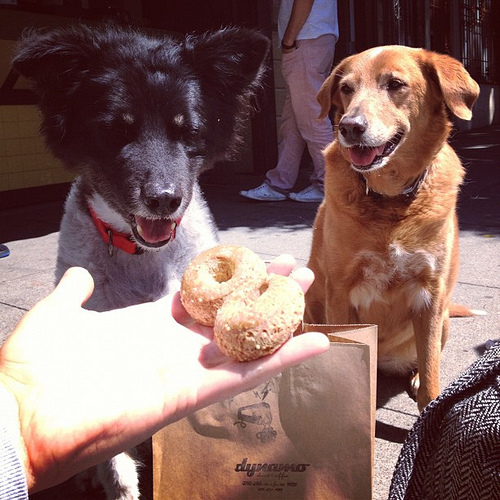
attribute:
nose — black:
[127, 171, 220, 224]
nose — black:
[333, 121, 376, 153]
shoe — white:
[286, 184, 323, 206]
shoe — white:
[239, 184, 285, 204]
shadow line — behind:
[1, 205, 499, 265]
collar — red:
[86, 192, 146, 264]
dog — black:
[59, 36, 274, 266]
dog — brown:
[299, 41, 490, 426]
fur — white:
[318, 147, 463, 389]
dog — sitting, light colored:
[293, 41, 488, 248]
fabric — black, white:
[387, 342, 498, 497]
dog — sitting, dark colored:
[0, 20, 279, 299]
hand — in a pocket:
[0, 249, 331, 484]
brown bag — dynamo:
[139, 356, 383, 491]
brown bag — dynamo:
[147, 309, 387, 498]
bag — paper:
[145, 322, 380, 498]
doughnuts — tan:
[180, 235, 312, 372]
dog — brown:
[319, 45, 480, 384]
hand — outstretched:
[2, 243, 342, 471]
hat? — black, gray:
[390, 348, 499, 499]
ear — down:
[418, 47, 482, 127]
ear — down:
[312, 55, 342, 124]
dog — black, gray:
[1, 25, 225, 499]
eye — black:
[382, 76, 409, 95]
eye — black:
[333, 79, 353, 97]